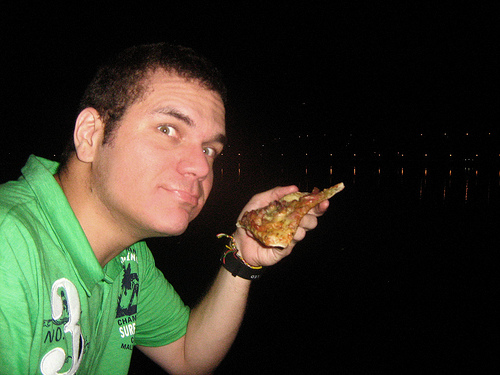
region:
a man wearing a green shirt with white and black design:
[0, 180, 179, 372]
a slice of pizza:
[241, 175, 343, 249]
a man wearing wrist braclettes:
[223, 226, 262, 288]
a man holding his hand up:
[116, 167, 341, 354]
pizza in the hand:
[240, 190, 331, 272]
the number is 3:
[50, 279, 103, 374]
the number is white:
[20, 274, 87, 369]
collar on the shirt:
[10, 157, 102, 299]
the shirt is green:
[21, 182, 118, 374]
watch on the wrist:
[222, 254, 263, 286]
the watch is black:
[222, 255, 263, 282]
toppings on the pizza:
[266, 202, 288, 235]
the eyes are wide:
[156, 120, 221, 160]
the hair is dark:
[89, 53, 230, 124]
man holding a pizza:
[94, 74, 351, 280]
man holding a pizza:
[82, 48, 344, 288]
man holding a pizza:
[85, 43, 355, 293]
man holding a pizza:
[68, 49, 365, 300]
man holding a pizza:
[54, 43, 351, 305]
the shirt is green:
[10, 165, 194, 374]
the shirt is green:
[11, 165, 197, 370]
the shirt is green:
[12, 170, 174, 372]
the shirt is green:
[9, 157, 194, 369]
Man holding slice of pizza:
[2, 49, 360, 373]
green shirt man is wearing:
[7, 155, 188, 373]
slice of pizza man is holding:
[242, 170, 342, 254]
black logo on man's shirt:
[114, 260, 137, 319]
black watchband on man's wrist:
[218, 242, 253, 277]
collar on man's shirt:
[24, 152, 115, 285]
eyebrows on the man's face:
[159, 102, 226, 142]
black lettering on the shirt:
[39, 317, 87, 338]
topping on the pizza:
[258, 186, 334, 235]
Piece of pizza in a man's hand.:
[240, 182, 347, 250]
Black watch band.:
[215, 248, 266, 281]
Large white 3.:
[40, 279, 85, 373]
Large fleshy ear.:
[73, 108, 103, 163]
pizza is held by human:
[239, 181, 346, 251]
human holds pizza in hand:
[2, 43, 344, 374]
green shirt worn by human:
[1, 154, 193, 374]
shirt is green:
[0, 154, 190, 374]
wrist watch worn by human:
[219, 248, 263, 288]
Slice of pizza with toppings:
[232, 182, 351, 248]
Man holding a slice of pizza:
[0, 48, 347, 373]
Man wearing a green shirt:
[0, 41, 344, 373]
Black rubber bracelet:
[216, 245, 260, 282]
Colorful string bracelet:
[212, 228, 265, 270]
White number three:
[29, 274, 89, 372]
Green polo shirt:
[0, 156, 187, 371]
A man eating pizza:
[0, 40, 347, 374]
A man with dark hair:
[2, 40, 350, 372]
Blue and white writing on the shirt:
[112, 251, 140, 348]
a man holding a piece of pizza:
[5, 33, 348, 368]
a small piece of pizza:
[240, 175, 355, 241]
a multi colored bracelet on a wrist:
[216, 220, 274, 273]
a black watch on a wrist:
[212, 232, 289, 283]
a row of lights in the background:
[209, 100, 496, 207]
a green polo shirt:
[1, 143, 214, 374]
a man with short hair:
[55, 35, 240, 237]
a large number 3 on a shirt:
[25, 256, 110, 373]